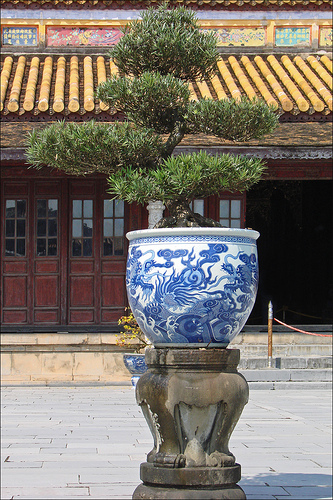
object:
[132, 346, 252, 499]
pedestal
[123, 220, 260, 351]
planter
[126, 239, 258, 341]
blue dragon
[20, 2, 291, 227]
bonsai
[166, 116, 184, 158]
sticks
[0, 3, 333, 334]
building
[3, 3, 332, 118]
roof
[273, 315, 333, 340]
rope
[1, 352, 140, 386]
wall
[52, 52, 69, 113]
rod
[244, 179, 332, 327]
entrance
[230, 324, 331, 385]
stairs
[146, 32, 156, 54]
green leaves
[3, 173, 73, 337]
door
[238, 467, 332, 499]
shadow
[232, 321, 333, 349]
stone